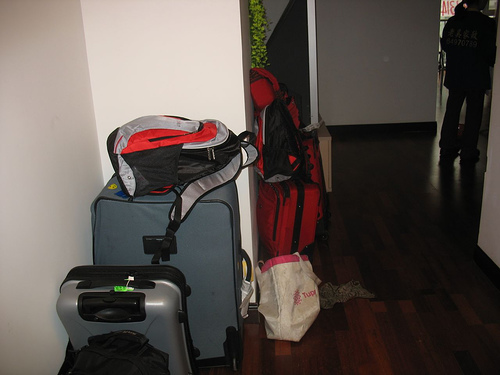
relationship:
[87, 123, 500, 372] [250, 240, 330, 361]
floor near bag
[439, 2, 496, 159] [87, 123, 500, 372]
person on floor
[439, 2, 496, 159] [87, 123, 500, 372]
person above floor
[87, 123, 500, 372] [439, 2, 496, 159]
floor below person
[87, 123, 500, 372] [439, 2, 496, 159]
floor under person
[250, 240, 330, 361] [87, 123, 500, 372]
bag on floor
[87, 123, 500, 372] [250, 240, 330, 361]
floor below bag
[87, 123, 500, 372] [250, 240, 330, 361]
floor under bag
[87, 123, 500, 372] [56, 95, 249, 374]
floor below luggage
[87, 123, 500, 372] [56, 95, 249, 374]
floor under luggage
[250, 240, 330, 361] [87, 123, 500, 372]
bag above floor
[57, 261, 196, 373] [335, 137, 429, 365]
suitcase on floor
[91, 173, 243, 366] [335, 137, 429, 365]
suitcase on floor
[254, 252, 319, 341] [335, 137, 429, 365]
bag on floor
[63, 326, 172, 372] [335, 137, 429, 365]
bag on floor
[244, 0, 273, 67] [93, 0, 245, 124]
green decoration hanging on wall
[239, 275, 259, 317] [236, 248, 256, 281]
white tag on handle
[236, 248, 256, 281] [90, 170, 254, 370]
handle of a suitcase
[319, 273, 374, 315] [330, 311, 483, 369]
brown scarf on floor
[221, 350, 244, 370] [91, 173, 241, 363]
wheel on suitcase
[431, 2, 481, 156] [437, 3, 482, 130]
person in doorway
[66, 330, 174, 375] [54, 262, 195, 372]
bag beside a suitcase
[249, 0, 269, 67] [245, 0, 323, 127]
green decoration peeking out of door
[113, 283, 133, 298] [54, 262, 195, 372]
tag on a suitcase